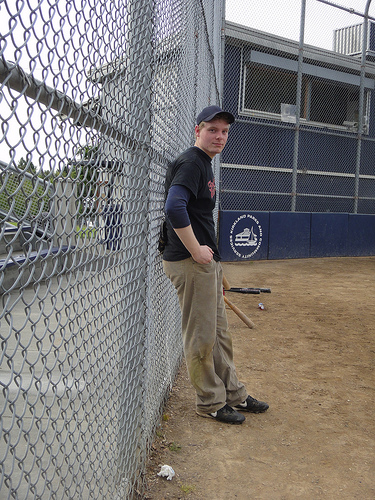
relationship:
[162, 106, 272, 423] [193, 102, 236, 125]
man wearing cap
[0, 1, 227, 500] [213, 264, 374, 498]
chain-link fence around field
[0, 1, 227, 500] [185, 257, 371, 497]
chain-link fence surrounding field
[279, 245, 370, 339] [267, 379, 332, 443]
ground made dirt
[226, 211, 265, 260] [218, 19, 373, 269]
logo on gate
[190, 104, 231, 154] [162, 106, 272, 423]
head of man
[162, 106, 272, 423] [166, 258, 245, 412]
man wearing pants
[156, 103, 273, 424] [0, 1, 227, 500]
man leaning on chain-link fence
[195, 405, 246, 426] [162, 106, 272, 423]
shoe of man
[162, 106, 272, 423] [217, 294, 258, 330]
man holding baseball bat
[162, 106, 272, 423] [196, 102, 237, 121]
man wearing cap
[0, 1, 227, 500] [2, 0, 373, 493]
chain-link fence surrounding field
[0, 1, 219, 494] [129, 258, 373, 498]
chain-link fence surrounding field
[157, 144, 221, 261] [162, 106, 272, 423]
shirt on man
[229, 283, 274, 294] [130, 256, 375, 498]
bats on ground